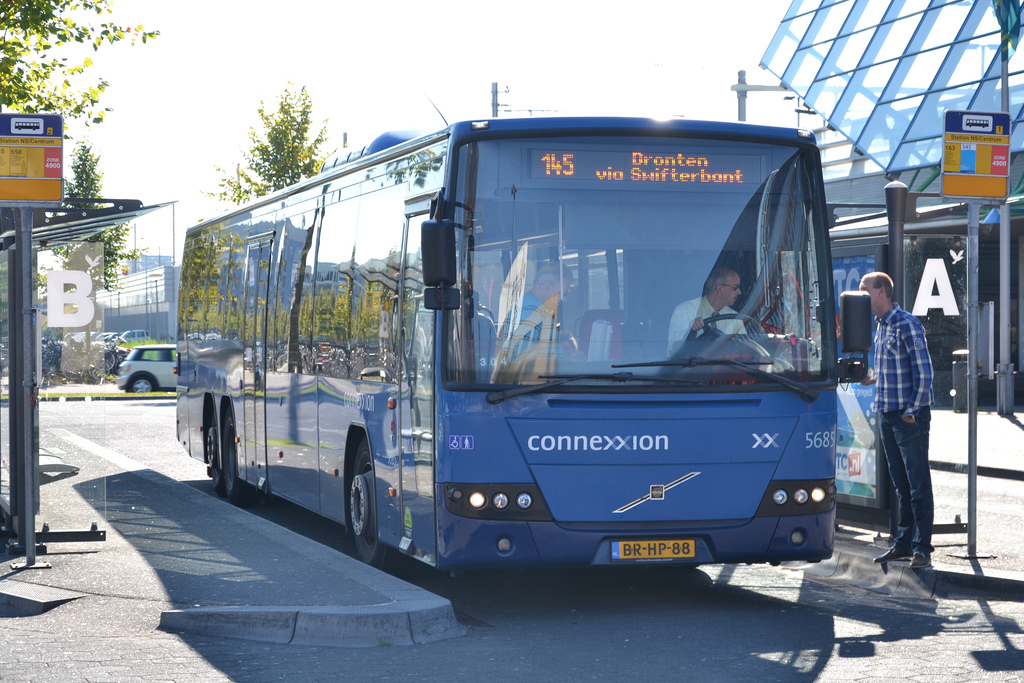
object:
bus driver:
[666, 268, 748, 362]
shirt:
[666, 295, 749, 357]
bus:
[169, 113, 876, 577]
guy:
[852, 269, 935, 568]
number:
[542, 153, 575, 176]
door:
[235, 232, 268, 490]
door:
[395, 194, 436, 567]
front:
[433, 117, 838, 561]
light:
[468, 490, 484, 508]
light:
[492, 493, 508, 510]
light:
[517, 493, 533, 510]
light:
[772, 489, 788, 506]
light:
[794, 489, 810, 504]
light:
[811, 487, 827, 503]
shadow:
[68, 465, 871, 683]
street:
[0, 390, 1024, 683]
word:
[525, 434, 672, 452]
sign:
[936, 107, 1008, 201]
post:
[964, 201, 980, 559]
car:
[113, 344, 176, 394]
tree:
[214, 78, 338, 211]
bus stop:
[2, 109, 178, 567]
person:
[499, 261, 575, 367]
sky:
[2, 1, 1024, 259]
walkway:
[3, 428, 452, 629]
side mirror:
[421, 220, 464, 311]